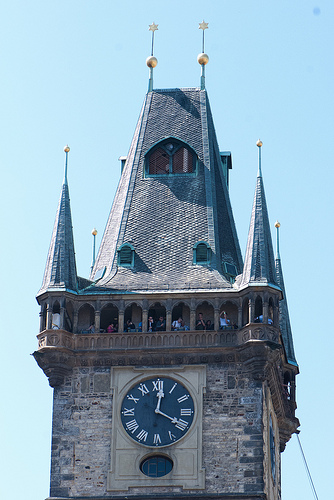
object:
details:
[135, 429, 149, 440]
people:
[82, 309, 238, 332]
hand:
[155, 390, 178, 424]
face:
[120, 376, 195, 449]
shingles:
[31, 87, 292, 293]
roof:
[80, 88, 240, 289]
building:
[30, 20, 301, 500]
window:
[122, 300, 144, 336]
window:
[148, 302, 168, 331]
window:
[170, 302, 191, 331]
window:
[194, 301, 215, 331]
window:
[240, 297, 250, 326]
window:
[253, 291, 263, 326]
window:
[266, 296, 275, 326]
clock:
[116, 370, 200, 450]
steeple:
[240, 140, 282, 287]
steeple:
[274, 218, 298, 366]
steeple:
[34, 145, 80, 301]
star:
[147, 20, 160, 31]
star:
[198, 19, 208, 31]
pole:
[150, 31, 155, 54]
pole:
[200, 29, 206, 52]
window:
[143, 136, 198, 176]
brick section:
[51, 363, 267, 499]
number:
[151, 379, 164, 392]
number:
[169, 382, 178, 393]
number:
[175, 393, 189, 403]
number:
[178, 406, 193, 416]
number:
[174, 418, 187, 431]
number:
[166, 429, 177, 441]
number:
[152, 433, 164, 445]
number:
[137, 430, 147, 445]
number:
[124, 418, 141, 435]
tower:
[31, 21, 302, 500]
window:
[138, 453, 174, 476]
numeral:
[166, 429, 176, 440]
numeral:
[179, 407, 197, 418]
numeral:
[123, 407, 135, 419]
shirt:
[107, 325, 115, 333]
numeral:
[178, 394, 192, 403]